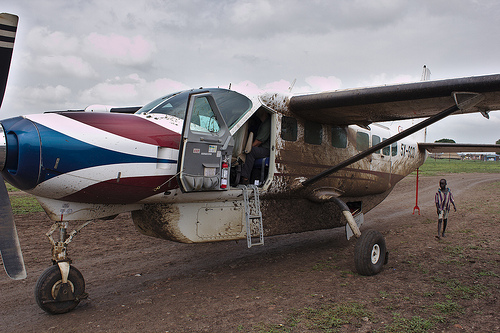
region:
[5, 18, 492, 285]
white, red, and blue airplane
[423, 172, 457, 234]
person next to plane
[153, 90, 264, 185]
cockpit of airplane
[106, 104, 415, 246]
dirt on side of airplane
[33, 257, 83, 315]
front wheel of airplane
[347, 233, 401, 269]
wheel on side of airplane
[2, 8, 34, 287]
propellor of airplane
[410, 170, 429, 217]
red cord hanging from plane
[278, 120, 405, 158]
windows on side of plane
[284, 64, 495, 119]
wing of airplane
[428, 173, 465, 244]
Small child walking in dirt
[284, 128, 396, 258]
Brown dirt covering the plane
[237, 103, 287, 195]
man sitting in the plane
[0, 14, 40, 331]
Propeller of the plane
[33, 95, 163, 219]
Blue white and red front of plane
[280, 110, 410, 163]
Small windows on the plane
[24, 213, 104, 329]
Black wheels on the plane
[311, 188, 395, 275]
Black wheels on the plane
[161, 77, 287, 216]
Door to the plane is open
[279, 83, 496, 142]
Large wing of the plane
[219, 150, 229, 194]
A red can of fire extinguisher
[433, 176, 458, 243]
Boy walking bare feet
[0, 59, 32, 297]
Propellers of an aeroplane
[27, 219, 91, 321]
Frontal landing gear of an aeroplane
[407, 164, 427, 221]
Red colored ribon hanging down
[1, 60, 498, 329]
Aeroplane standin on a runway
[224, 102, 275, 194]
Person seated inside a cockpit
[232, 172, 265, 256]
Short ladder hanging from a doorway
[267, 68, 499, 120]
Fixed wing of an aeroplane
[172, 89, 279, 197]
Open door of an aeroplane and the doorway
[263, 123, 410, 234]
mud on the side of an airplane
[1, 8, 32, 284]
propeller on the nose of an airplane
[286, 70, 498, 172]
airplane wing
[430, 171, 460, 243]
boy walking in mud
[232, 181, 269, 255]
ladder hanging on an airplane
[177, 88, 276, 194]
open door on an airplane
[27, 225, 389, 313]
black, rubber airplane wheels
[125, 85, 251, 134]
airplane windshield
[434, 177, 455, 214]
boy in a striped shirt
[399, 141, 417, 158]
number on the back of an airplane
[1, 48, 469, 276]
a dirty muddy plane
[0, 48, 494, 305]
a white, blue, and red plane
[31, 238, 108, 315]
a front muddy tire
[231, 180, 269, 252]
a small ladder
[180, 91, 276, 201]
an opened plane door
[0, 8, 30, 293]
a front perpeller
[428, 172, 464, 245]
a little boy walking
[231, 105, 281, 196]
a man inside a plane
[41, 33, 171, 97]
fluffy white clouds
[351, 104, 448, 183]
the back of a plane